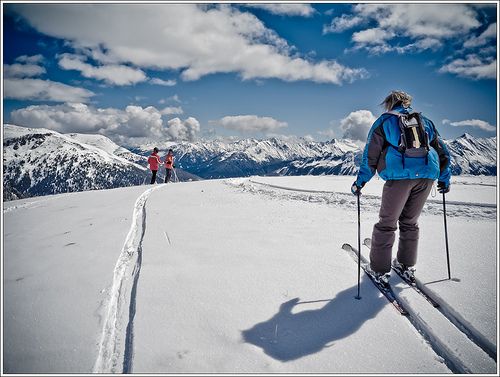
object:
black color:
[370, 126, 388, 169]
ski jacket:
[355, 105, 451, 189]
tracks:
[338, 245, 491, 370]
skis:
[331, 233, 495, 371]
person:
[143, 145, 164, 186]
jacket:
[144, 154, 162, 170]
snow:
[86, 194, 344, 319]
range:
[13, 100, 478, 211]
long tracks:
[91, 182, 149, 373]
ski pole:
[347, 195, 372, 306]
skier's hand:
[346, 177, 369, 198]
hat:
[149, 145, 164, 155]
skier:
[355, 90, 462, 319]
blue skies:
[193, 82, 311, 115]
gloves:
[350, 180, 363, 195]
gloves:
[437, 182, 449, 193]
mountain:
[13, 115, 143, 185]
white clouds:
[12, 10, 496, 83]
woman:
[349, 88, 456, 298]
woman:
[166, 142, 177, 182]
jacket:
[165, 152, 174, 165]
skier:
[162, 147, 174, 183]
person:
[147, 144, 162, 183]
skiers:
[147, 147, 166, 182]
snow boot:
[358, 259, 390, 286]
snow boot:
[388, 255, 416, 282]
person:
[348, 86, 458, 301]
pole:
[346, 186, 373, 308]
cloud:
[148, 75, 177, 87]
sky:
[5, 3, 495, 145]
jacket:
[352, 106, 452, 181]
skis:
[127, 172, 189, 192]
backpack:
[399, 110, 430, 159]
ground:
[55, 219, 341, 374]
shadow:
[238, 276, 395, 364]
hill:
[35, 122, 141, 181]